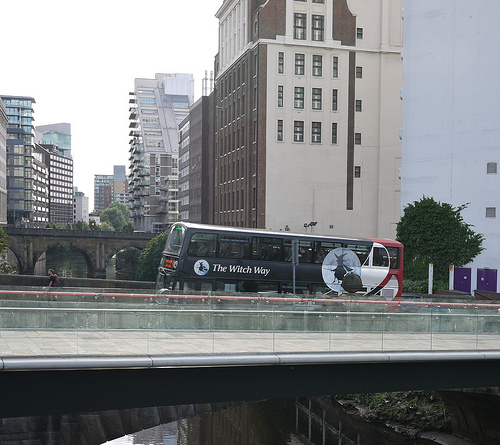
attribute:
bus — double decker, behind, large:
[153, 219, 407, 308]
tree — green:
[397, 198, 468, 296]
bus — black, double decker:
[146, 212, 428, 305]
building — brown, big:
[204, 42, 404, 224]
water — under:
[192, 367, 386, 432]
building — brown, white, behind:
[207, 2, 417, 254]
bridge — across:
[0, 227, 157, 277]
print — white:
[212, 256, 229, 277]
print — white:
[211, 264, 271, 276]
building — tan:
[249, 0, 399, 240]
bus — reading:
[144, 222, 484, 318]